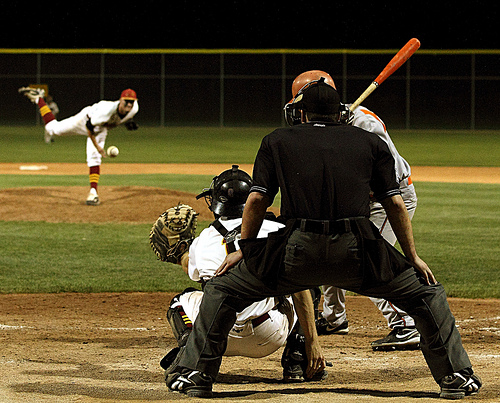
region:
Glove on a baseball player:
[141, 194, 208, 278]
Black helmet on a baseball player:
[192, 157, 267, 239]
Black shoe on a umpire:
[146, 348, 226, 401]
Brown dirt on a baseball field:
[28, 301, 161, 388]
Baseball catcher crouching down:
[132, 154, 346, 371]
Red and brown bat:
[308, 36, 441, 130]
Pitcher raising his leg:
[16, 81, 178, 211]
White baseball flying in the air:
[96, 141, 160, 195]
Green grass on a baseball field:
[8, 218, 163, 315]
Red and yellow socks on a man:
[71, 161, 113, 234]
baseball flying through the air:
[92, 140, 127, 172]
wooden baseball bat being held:
[337, 15, 444, 163]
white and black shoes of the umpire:
[149, 365, 229, 400]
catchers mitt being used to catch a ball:
[137, 194, 207, 277]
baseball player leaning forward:
[16, 61, 143, 221]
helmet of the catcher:
[197, 167, 263, 232]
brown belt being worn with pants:
[217, 302, 289, 336]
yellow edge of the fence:
[3, 40, 498, 70]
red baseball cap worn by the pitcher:
[112, 82, 149, 111]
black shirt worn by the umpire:
[235, 115, 415, 229]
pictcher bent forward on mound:
[16, 79, 150, 209]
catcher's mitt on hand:
[145, 193, 201, 269]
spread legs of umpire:
[160, 262, 488, 394]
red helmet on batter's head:
[287, 62, 347, 98]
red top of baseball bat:
[369, 29, 439, 97]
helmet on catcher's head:
[208, 163, 254, 224]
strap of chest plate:
[212, 223, 240, 253]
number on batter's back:
[360, 105, 389, 132]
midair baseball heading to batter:
[103, 134, 128, 169]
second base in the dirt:
[15, 151, 62, 179]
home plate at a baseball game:
[150, 33, 477, 401]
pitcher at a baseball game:
[12, 65, 159, 217]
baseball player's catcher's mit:
[140, 193, 205, 270]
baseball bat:
[317, 24, 444, 143]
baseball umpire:
[188, 84, 490, 401]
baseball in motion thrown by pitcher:
[98, 135, 127, 163]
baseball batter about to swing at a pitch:
[265, 31, 475, 361]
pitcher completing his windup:
[12, 61, 164, 211]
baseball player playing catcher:
[136, 164, 329, 391]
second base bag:
[14, 153, 54, 180]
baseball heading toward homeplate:
[92, 141, 139, 166]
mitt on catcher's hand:
[143, 196, 201, 273]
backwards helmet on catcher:
[201, 162, 251, 227]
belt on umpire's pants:
[296, 209, 357, 244]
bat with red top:
[351, 34, 425, 115]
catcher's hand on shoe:
[294, 334, 343, 384]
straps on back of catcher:
[214, 220, 241, 257]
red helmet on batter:
[283, 65, 336, 93]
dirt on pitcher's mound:
[18, 183, 153, 217]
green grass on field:
[422, 192, 488, 246]